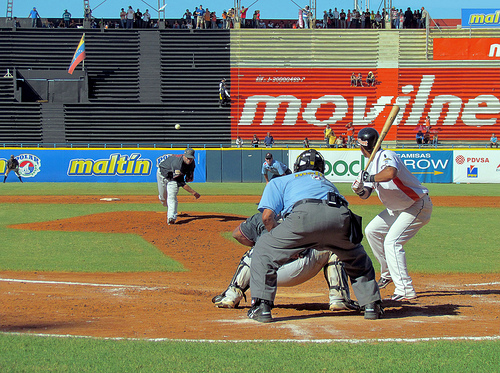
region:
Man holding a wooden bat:
[344, 90, 399, 191]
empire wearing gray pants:
[240, 197, 396, 314]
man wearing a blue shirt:
[268, 167, 338, 208]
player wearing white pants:
[356, 184, 428, 294]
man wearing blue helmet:
[354, 122, 381, 156]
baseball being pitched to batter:
[175, 117, 179, 132]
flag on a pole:
[58, 19, 90, 80]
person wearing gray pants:
[138, 165, 190, 217]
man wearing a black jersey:
[161, 148, 204, 190]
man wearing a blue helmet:
[356, 125, 380, 157]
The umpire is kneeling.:
[235, 146, 389, 328]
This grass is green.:
[39, 241, 139, 263]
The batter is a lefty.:
[350, 104, 445, 304]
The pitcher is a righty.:
[153, 143, 208, 223]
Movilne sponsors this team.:
[233, 71, 498, 139]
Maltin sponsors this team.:
[68, 150, 156, 178]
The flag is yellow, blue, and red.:
[65, 30, 90, 80]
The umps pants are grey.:
[250, 200, 385, 307]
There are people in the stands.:
[300, 3, 432, 24]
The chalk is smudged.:
[0, 275, 174, 292]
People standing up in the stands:
[24, 4, 56, 30]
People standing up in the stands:
[53, 1, 83, 25]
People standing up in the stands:
[89, 6, 150, 37]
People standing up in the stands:
[164, 8, 213, 24]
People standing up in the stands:
[206, 5, 251, 32]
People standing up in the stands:
[249, 3, 321, 32]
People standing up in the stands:
[317, 3, 360, 26]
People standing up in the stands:
[353, 8, 432, 25]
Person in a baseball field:
[146, 136, 193, 239]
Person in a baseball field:
[238, 118, 329, 320]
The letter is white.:
[461, 83, 498, 135]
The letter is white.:
[422, 85, 466, 132]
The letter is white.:
[405, 66, 437, 136]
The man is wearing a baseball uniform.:
[350, 94, 438, 314]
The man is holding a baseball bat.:
[339, 93, 444, 323]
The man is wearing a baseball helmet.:
[338, 97, 441, 312]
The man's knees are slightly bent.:
[351, 96, 443, 313]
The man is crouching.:
[239, 138, 381, 328]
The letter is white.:
[234, 83, 306, 138]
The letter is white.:
[300, 88, 354, 135]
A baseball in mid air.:
[149, 107, 200, 142]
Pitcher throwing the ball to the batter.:
[153, 113, 209, 225]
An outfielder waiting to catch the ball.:
[2, 146, 29, 186]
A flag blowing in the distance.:
[60, 22, 107, 100]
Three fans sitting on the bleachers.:
[341, 65, 385, 93]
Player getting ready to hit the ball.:
[357, 72, 434, 314]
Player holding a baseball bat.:
[347, 94, 405, 195]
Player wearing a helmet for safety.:
[354, 115, 386, 161]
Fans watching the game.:
[302, 8, 441, 44]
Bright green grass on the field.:
[432, 213, 489, 272]